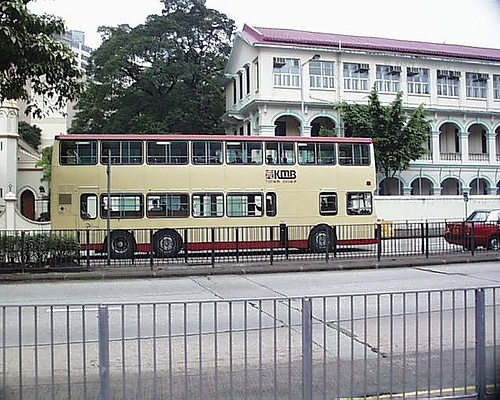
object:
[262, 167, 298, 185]
writing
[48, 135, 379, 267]
bus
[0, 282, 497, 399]
railing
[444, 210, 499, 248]
car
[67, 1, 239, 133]
tree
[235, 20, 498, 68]
roof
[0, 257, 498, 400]
pavement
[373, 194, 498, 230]
wall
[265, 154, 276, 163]
person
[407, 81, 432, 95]
rails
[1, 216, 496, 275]
fence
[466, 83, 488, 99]
balcony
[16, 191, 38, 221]
door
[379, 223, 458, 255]
road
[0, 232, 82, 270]
bushes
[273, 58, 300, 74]
window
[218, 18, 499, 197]
building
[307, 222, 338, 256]
tire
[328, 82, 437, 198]
tree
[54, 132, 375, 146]
roof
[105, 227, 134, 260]
front wheel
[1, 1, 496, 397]
photo